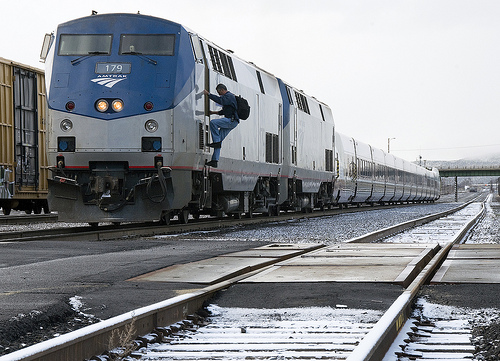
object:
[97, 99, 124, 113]
train headlights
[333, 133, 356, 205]
train car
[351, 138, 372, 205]
train car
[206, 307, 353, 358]
snow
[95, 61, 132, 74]
train number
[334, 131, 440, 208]
passenger cars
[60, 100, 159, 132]
train headlights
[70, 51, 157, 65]
windshield wipers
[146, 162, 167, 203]
wires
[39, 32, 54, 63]
mirror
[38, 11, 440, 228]
train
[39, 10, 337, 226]
powerful locomotive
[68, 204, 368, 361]
railroad tracks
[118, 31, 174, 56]
train window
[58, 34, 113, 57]
train window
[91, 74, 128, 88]
decal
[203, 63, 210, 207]
ladder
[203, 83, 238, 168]
man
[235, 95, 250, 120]
backpack